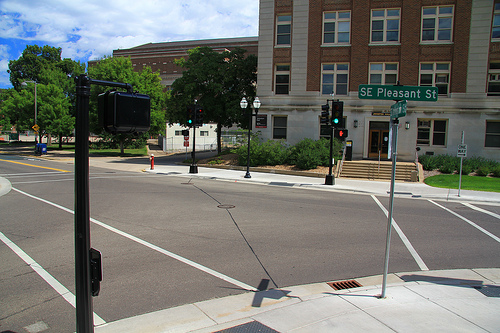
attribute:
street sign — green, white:
[353, 83, 438, 103]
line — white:
[1, 229, 107, 325]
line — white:
[10, 183, 259, 294]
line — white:
[370, 191, 429, 273]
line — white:
[424, 195, 499, 252]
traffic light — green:
[332, 117, 340, 127]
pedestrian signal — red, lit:
[336, 128, 348, 137]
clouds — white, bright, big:
[0, 0, 259, 90]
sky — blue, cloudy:
[1, 2, 260, 90]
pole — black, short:
[69, 71, 100, 332]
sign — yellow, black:
[29, 120, 40, 133]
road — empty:
[1, 151, 498, 333]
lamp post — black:
[241, 108, 260, 179]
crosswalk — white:
[1, 183, 257, 323]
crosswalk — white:
[373, 189, 499, 276]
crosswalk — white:
[11, 166, 168, 183]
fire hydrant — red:
[148, 153, 156, 170]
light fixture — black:
[329, 97, 345, 127]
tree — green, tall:
[165, 44, 256, 154]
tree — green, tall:
[79, 57, 167, 154]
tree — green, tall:
[1, 80, 71, 150]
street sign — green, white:
[384, 98, 408, 122]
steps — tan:
[335, 155, 423, 185]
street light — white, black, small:
[238, 92, 261, 180]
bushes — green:
[235, 131, 343, 171]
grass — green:
[422, 170, 498, 193]